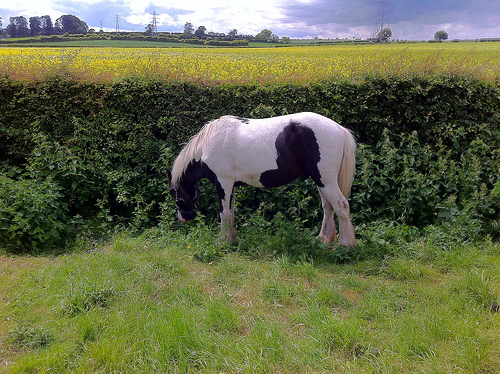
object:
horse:
[166, 111, 359, 258]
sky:
[2, 3, 500, 38]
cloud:
[126, 3, 307, 36]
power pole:
[150, 10, 158, 32]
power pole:
[115, 12, 121, 31]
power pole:
[99, 15, 104, 31]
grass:
[0, 221, 499, 373]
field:
[2, 41, 499, 85]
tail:
[339, 128, 358, 201]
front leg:
[219, 178, 232, 246]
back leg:
[318, 179, 356, 247]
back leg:
[315, 182, 337, 244]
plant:
[95, 197, 115, 233]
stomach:
[239, 173, 308, 187]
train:
[479, 38, 499, 41]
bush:
[1, 73, 499, 157]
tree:
[55, 14, 89, 34]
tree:
[194, 24, 209, 40]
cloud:
[278, 1, 497, 36]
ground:
[6, 37, 201, 49]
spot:
[262, 121, 329, 190]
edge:
[488, 83, 500, 137]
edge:
[348, 131, 360, 173]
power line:
[116, 11, 152, 18]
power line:
[82, 22, 102, 28]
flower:
[90, 60, 96, 72]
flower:
[149, 63, 153, 69]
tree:
[434, 30, 448, 42]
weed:
[56, 62, 75, 84]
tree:
[146, 21, 157, 35]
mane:
[172, 117, 219, 185]